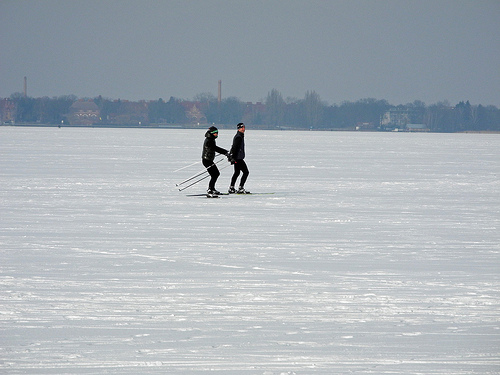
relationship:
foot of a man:
[227, 187, 239, 194] [229, 123, 250, 194]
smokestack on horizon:
[216, 77, 224, 108] [7, 73, 497, 113]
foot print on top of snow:
[131, 346, 178, 358] [1, 128, 498, 374]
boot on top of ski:
[227, 185, 240, 193] [218, 190, 276, 196]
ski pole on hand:
[175, 156, 224, 187] [201, 153, 215, 165]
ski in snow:
[218, 190, 276, 196] [1, 128, 498, 374]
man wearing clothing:
[229, 123, 250, 194] [230, 132, 249, 188]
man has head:
[229, 123, 250, 194] [234, 124, 246, 133]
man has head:
[229, 123, 250, 194] [235, 120, 245, 133]